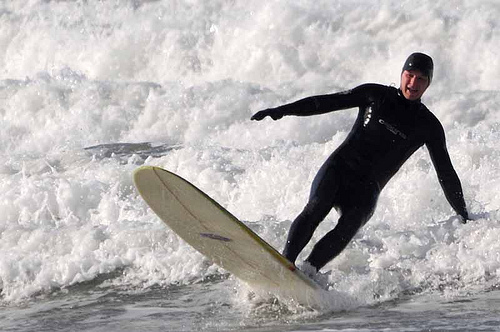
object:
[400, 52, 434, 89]
cap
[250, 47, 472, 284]
man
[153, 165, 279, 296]
line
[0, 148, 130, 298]
foam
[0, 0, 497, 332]
ocean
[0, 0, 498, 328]
water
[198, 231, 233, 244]
logo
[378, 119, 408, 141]
logo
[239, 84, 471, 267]
body suit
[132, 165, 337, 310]
board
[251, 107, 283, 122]
glove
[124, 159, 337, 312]
surfboard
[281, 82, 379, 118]
arm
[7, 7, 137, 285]
wave